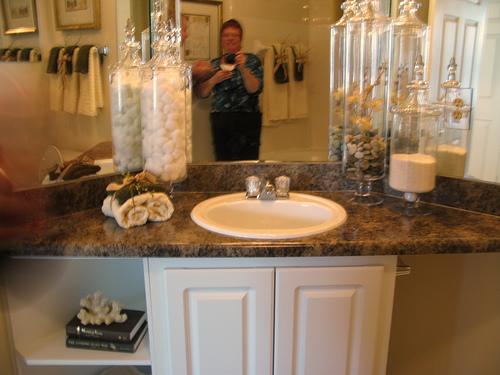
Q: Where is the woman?
A: In the bathroom.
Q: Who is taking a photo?
A: A woman.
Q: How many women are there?
A: One.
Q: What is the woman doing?
A: Taking a picture.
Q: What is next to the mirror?
A: Vases.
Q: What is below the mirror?
A: A sink.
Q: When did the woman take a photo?
A: Just now.